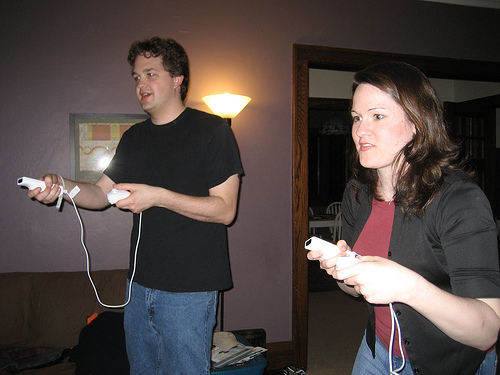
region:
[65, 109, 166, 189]
Picture on a wall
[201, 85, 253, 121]
Light on behind man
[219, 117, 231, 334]
Black light pole behind man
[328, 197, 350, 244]
White wooden chair at a table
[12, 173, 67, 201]
White wii mote in a man's hand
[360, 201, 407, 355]
Maroon shirt on a woman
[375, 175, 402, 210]
Necklace on a woman's neck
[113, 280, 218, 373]
Man wearing blue jeans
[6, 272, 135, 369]
Brown covering on a couch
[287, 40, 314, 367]
Brown wood framing a doorway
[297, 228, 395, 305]
Gain controller held by female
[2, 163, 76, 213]
Game controller held by male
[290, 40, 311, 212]
Woodwork around the door frame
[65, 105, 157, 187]
Picture hanging on the wall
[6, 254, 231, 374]
Couch sitting against the wall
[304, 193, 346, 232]
Kitchen table in an adjoining room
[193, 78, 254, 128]
Light hanging on the wall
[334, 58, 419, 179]
Look of concentration on game players face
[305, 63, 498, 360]
Female playing video games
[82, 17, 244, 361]
Male playing video games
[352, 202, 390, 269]
the shirt is red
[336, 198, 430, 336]
the shirt is red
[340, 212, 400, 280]
the shirt is red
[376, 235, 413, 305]
the shirt is red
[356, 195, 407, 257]
the shirt is red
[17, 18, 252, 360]
man playing the wii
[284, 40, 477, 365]
woman playing the wii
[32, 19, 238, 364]
man wearing black shirt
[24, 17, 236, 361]
man wearing jean pants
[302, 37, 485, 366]
woman wearing jean pants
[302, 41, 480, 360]
woman wearing red shirt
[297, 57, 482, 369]
woman wearing black shirt with buttons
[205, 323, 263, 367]
stack a papers in a bin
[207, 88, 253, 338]
black slim light with white cover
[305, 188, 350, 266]
white dining room table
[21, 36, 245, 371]
a man playing wii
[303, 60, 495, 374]
a woman playing wii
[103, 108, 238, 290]
a shirt sleeved black shirt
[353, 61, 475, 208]
the woman's brown hair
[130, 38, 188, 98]
the man's brown hair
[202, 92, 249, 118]
the lamp turned on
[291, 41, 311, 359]
the wood trim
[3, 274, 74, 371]
the brown couch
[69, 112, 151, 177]
the frame on the wall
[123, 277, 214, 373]
the man's denim pants